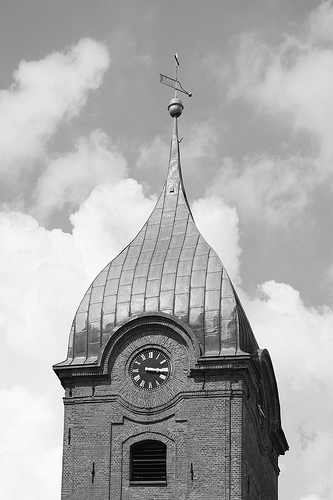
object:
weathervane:
[157, 49, 196, 118]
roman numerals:
[147, 350, 156, 362]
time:
[137, 362, 169, 374]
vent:
[128, 435, 167, 485]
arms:
[143, 364, 167, 374]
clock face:
[127, 345, 173, 391]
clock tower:
[55, 48, 292, 497]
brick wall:
[64, 380, 238, 496]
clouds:
[5, 35, 147, 275]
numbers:
[143, 347, 167, 365]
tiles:
[59, 161, 284, 369]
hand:
[142, 360, 172, 378]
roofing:
[88, 167, 272, 338]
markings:
[144, 366, 172, 376]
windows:
[113, 433, 183, 497]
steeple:
[61, 49, 279, 370]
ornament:
[127, 41, 221, 133]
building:
[37, 95, 273, 486]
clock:
[124, 340, 203, 401]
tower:
[49, 50, 289, 498]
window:
[126, 437, 169, 486]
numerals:
[137, 350, 162, 361]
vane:
[157, 49, 193, 99]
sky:
[1, 1, 321, 498]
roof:
[50, 113, 292, 453]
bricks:
[108, 326, 190, 408]